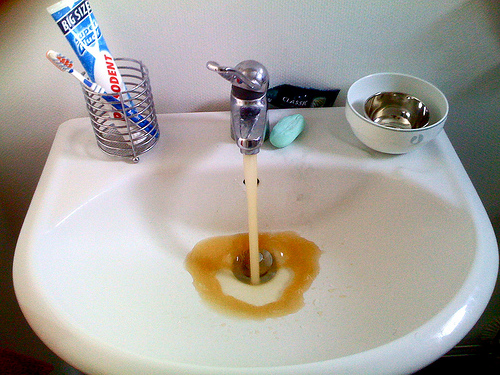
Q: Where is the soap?
A: By the faucet.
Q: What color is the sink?
A: White.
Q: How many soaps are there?
A: One.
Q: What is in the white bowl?
A: Silver cup.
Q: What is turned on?
A: Faucet.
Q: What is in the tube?
A: Fixodent.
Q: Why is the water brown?
A: Bad pipes.